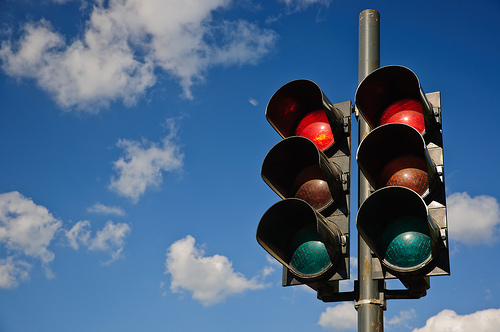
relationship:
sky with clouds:
[0, 0, 500, 332] [7, 4, 222, 106]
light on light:
[280, 226, 336, 282] [255, 79, 359, 291]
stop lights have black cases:
[242, 67, 468, 289] [279, 148, 401, 249]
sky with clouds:
[213, 117, 256, 173] [47, 10, 237, 119]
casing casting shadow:
[259, 72, 336, 134] [281, 100, 300, 117]